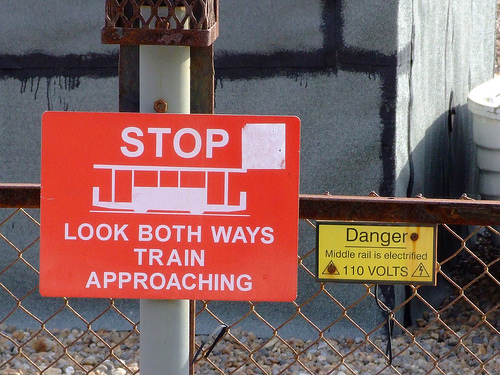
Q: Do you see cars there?
A: No, there are no cars.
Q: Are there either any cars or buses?
A: No, there are no cars or buses.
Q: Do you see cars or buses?
A: No, there are no cars or buses.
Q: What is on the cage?
A: The sign is on the cage.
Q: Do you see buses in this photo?
A: No, there are no buses.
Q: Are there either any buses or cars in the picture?
A: No, there are no buses or cars.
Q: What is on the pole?
A: The sign is on the pole.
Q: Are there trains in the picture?
A: Yes, there is a train.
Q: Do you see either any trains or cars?
A: Yes, there is a train.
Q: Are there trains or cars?
A: Yes, there is a train.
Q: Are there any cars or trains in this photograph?
A: Yes, there is a train.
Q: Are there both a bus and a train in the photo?
A: No, there is a train but no buses.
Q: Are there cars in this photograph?
A: No, there are no cars.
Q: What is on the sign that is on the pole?
A: The train is on the sign.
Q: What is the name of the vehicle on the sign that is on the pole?
A: The vehicle is a train.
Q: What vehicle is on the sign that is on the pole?
A: The vehicle is a train.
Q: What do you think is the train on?
A: The train is on the sign.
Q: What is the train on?
A: The train is on the sign.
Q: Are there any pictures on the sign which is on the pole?
A: No, there is a train on the sign.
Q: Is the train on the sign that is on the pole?
A: Yes, the train is on the sign.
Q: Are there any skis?
A: No, there are no skis.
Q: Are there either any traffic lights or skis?
A: No, there are no skis or traffic lights.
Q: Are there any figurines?
A: No, there are no figurines.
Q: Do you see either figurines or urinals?
A: No, there are no figurines or urinals.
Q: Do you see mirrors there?
A: No, there are no mirrors.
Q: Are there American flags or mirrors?
A: No, there are no mirrors or American flags.